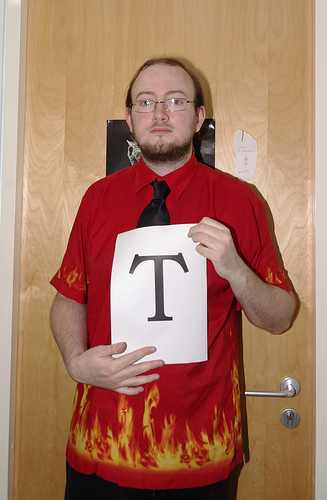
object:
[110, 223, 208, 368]
paper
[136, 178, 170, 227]
tie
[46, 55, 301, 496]
man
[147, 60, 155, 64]
hair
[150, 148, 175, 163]
hair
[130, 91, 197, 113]
glasses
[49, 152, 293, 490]
shirt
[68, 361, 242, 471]
flames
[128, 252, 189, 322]
t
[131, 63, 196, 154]
face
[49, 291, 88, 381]
arm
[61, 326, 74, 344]
hair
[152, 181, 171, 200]
knot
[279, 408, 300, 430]
lock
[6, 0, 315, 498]
door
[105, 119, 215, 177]
poster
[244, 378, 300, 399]
handle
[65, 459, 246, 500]
pants